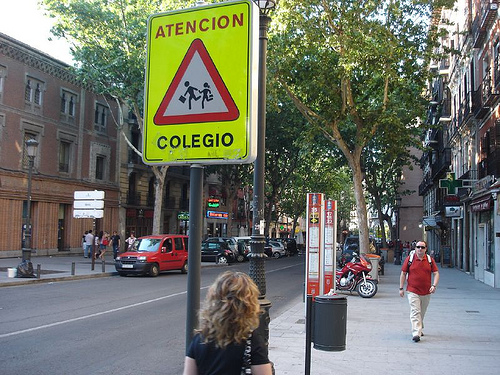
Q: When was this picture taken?
A: During the day.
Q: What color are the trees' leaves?
A: Green.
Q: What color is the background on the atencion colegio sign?
A: Yellow.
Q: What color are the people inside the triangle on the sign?
A: Black.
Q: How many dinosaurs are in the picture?
A: Zero.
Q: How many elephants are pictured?
A: Zero.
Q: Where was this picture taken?
A: A city street.